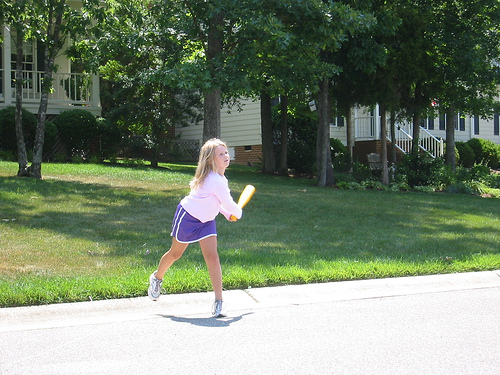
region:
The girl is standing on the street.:
[122, 107, 309, 332]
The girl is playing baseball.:
[132, 121, 285, 329]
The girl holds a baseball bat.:
[220, 170, 272, 227]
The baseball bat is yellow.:
[220, 175, 263, 225]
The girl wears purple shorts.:
[163, 197, 218, 247]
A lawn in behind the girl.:
[1, 165, 492, 305]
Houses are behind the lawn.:
[0, 35, 497, 169]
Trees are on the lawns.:
[7, 1, 494, 178]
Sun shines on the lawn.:
[0, 157, 499, 310]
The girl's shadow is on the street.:
[140, 296, 267, 331]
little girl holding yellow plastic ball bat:
[103, 135, 285, 337]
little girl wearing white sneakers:
[120, 143, 261, 329]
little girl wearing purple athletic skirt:
[142, 205, 219, 260]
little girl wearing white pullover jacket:
[149, 132, 288, 231]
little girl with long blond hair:
[161, 138, 258, 200]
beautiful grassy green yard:
[258, 177, 455, 269]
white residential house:
[153, 46, 495, 140]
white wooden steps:
[338, 119, 455, 176]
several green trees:
[151, 18, 488, 189]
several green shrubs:
[0, 109, 136, 170]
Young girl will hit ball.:
[144, 125, 262, 333]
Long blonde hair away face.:
[177, 133, 239, 195]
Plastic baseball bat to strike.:
[210, 140, 269, 231]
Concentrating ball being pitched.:
[187, 130, 242, 180]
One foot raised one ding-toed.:
[142, 264, 252, 324]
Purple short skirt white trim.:
[163, 203, 227, 251]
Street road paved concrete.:
[12, 317, 430, 372]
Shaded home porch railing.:
[7, 8, 147, 203]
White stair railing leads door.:
[351, 99, 478, 198]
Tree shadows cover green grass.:
[262, 112, 497, 264]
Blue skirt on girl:
[191, 214, 252, 297]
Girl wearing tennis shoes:
[128, 246, 272, 338]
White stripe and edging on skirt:
[158, 202, 231, 251]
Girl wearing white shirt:
[173, 174, 270, 231]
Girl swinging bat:
[229, 200, 294, 266]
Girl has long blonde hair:
[176, 132, 230, 232]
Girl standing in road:
[118, 212, 242, 313]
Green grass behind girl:
[72, 120, 280, 247]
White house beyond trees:
[229, 97, 383, 186]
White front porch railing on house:
[34, 90, 114, 107]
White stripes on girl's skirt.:
[174, 205, 186, 242]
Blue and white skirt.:
[170, 206, 217, 243]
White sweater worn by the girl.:
[190, 177, 241, 224]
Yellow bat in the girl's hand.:
[234, 180, 261, 227]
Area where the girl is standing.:
[117, 296, 252, 332]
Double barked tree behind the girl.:
[9, 26, 68, 180]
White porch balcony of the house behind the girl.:
[1, 51, 103, 116]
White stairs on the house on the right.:
[363, 118, 448, 168]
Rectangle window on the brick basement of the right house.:
[241, 145, 255, 153]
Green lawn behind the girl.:
[3, 161, 499, 275]